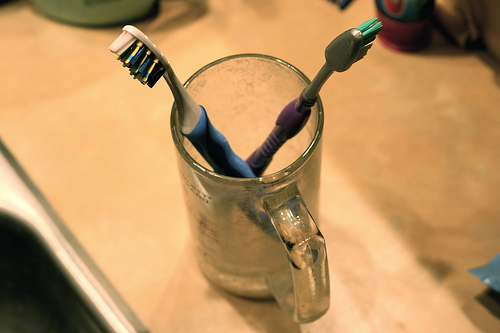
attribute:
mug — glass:
[150, 40, 361, 324]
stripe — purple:
[256, 128, 280, 155]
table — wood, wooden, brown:
[10, 17, 490, 324]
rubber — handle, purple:
[247, 96, 313, 173]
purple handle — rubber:
[249, 97, 306, 172]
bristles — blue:
[346, 12, 389, 39]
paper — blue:
[465, 250, 497, 285]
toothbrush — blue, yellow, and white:
[112, 8, 263, 224]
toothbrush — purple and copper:
[245, 13, 387, 180]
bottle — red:
[373, 0, 489, 57]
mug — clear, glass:
[169, 52, 331, 324]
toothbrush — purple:
[253, 15, 381, 169]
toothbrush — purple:
[92, 17, 267, 174]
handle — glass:
[262, 182, 331, 325]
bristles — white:
[104, 44, 156, 91]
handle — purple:
[230, 88, 318, 173]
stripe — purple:
[258, 132, 285, 159]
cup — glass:
[149, 47, 339, 324]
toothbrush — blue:
[112, 20, 306, 249]